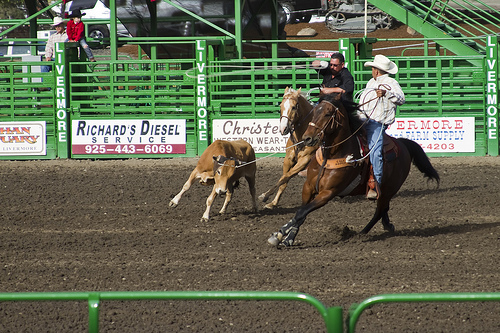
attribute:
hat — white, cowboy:
[357, 49, 402, 78]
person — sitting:
[39, 13, 71, 69]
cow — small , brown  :
[153, 131, 265, 231]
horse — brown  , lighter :
[268, 84, 326, 218]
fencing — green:
[2, 42, 498, 154]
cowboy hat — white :
[361, 50, 402, 79]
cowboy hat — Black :
[62, 4, 89, 24]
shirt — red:
[62, 13, 92, 53]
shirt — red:
[55, 13, 89, 51]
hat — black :
[61, 8, 91, 20]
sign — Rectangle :
[62, 108, 185, 166]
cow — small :
[161, 140, 261, 216]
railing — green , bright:
[4, 59, 496, 166]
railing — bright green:
[102, 80, 151, 89]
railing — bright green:
[53, 68, 111, 91]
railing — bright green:
[59, 79, 117, 100]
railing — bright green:
[4, 285, 479, 322]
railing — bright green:
[17, 283, 325, 331]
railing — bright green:
[344, 288, 459, 328]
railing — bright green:
[209, 35, 357, 152]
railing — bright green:
[364, 39, 478, 133]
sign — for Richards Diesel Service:
[68, 107, 190, 165]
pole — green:
[190, 36, 209, 166]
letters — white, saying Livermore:
[191, 39, 205, 143]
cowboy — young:
[59, 10, 98, 60]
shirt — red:
[63, 9, 86, 43]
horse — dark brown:
[261, 86, 444, 264]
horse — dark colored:
[250, 95, 453, 250]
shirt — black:
[311, 55, 358, 115]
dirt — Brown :
[4, 158, 496, 328]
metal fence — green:
[3, 19, 498, 179]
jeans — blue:
[359, 109, 395, 199]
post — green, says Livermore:
[49, 36, 81, 173]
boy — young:
[61, 6, 100, 68]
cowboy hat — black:
[61, 3, 91, 28]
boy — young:
[57, 11, 98, 70]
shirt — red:
[62, 17, 85, 39]